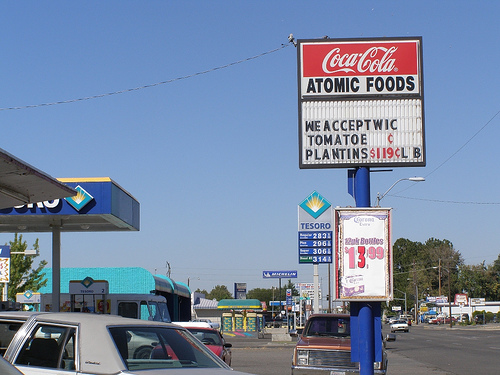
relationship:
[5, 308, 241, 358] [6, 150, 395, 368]
car at station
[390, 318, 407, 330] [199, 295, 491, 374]
car in street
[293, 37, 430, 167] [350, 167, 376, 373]
sign in pole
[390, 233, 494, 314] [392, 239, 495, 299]
tree with leaves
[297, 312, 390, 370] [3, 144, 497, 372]
car at station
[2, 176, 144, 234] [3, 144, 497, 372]
awning at station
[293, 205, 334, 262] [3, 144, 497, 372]
prices at station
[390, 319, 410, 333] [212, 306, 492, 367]
car on road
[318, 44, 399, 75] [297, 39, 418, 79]
logo on rectangle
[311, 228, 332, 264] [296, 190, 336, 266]
numbers on sign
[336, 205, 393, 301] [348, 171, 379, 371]
sign on pole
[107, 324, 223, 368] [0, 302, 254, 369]
back window of car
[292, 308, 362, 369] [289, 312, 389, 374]
front of car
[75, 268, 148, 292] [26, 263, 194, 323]
side of building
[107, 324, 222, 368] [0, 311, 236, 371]
back window of car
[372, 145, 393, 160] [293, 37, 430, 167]
numbers on sign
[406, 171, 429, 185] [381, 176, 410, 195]
street light on pole